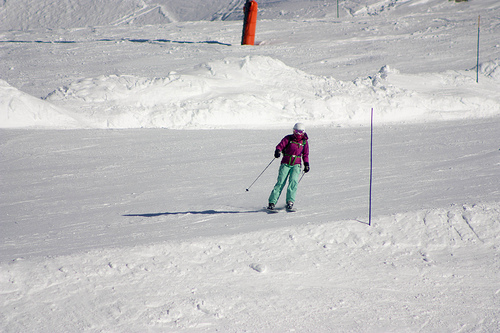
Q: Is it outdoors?
A: Yes, it is outdoors.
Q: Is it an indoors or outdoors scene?
A: It is outdoors.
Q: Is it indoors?
A: No, it is outdoors.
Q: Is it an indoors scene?
A: No, it is outdoors.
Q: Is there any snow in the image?
A: Yes, there is snow.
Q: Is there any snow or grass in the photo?
A: Yes, there is snow.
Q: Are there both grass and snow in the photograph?
A: No, there is snow but no grass.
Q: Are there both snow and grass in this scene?
A: No, there is snow but no grass.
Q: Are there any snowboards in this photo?
A: No, there are no snowboards.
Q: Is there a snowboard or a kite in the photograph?
A: No, there are no snowboards or kites.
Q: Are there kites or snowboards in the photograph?
A: No, there are no snowboards or kites.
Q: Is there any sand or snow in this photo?
A: Yes, there is snow.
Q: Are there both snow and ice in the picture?
A: No, there is snow but no ice.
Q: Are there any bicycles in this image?
A: No, there are no bicycles.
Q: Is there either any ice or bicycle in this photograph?
A: No, there are no bicycles or ice.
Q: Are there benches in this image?
A: No, there are no benches.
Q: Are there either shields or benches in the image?
A: No, there are no benches or shields.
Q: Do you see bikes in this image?
A: No, there are no bikes.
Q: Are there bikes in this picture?
A: No, there are no bikes.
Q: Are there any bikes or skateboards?
A: No, there are no bikes or skateboards.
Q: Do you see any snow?
A: Yes, there is snow.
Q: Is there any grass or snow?
A: Yes, there is snow.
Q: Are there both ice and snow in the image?
A: No, there is snow but no ice.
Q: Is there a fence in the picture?
A: No, there are no fences.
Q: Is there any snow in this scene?
A: Yes, there is snow.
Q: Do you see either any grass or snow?
A: Yes, there is snow.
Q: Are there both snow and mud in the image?
A: No, there is snow but no mud.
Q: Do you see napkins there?
A: No, there are no napkins.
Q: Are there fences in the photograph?
A: No, there are no fences.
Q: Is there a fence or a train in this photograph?
A: No, there are no fences or trains.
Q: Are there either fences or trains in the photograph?
A: No, there are no fences or trains.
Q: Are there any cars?
A: No, there are no cars.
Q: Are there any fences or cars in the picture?
A: No, there are no cars or fences.